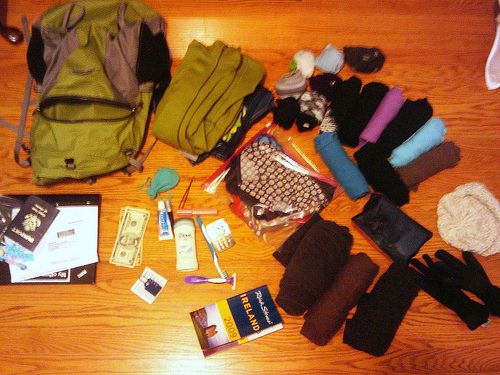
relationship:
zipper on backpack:
[120, 96, 155, 115] [2, 2, 172, 187]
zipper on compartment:
[120, 96, 155, 115] [26, 100, 143, 182]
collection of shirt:
[270, 65, 463, 356] [261, 207, 359, 325]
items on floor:
[108, 143, 281, 316] [80, 297, 137, 337]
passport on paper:
[3, 196, 57, 252] [3, 207, 96, 283]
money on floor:
[109, 206, 151, 268] [58, 308, 141, 350]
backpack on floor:
[17, 4, 174, 193] [2, 0, 497, 352]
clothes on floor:
[303, 69, 465, 196] [30, 300, 106, 372]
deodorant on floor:
[159, 203, 212, 283] [13, 303, 98, 373]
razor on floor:
[181, 272, 241, 292] [429, 24, 464, 74]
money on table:
[104, 205, 152, 268] [13, 306, 88, 373]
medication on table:
[206, 212, 243, 265] [27, 316, 99, 365]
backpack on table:
[17, 4, 174, 193] [27, 300, 88, 372]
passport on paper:
[3, 194, 60, 252] [7, 204, 99, 281]